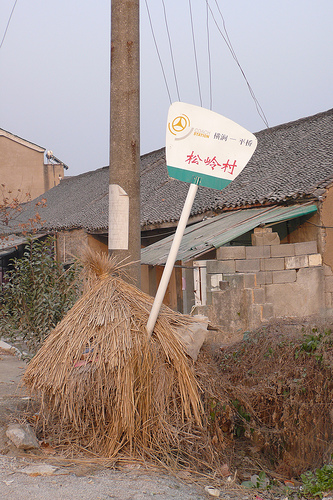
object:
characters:
[237, 137, 247, 149]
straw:
[12, 231, 227, 477]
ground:
[0, 328, 332, 500]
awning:
[138, 203, 322, 267]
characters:
[220, 158, 239, 179]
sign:
[164, 101, 259, 192]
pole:
[144, 183, 196, 338]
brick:
[293, 241, 316, 260]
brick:
[258, 258, 283, 273]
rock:
[4, 424, 41, 453]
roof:
[0, 110, 332, 235]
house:
[0, 110, 332, 364]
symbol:
[166, 112, 195, 141]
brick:
[242, 271, 256, 286]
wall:
[193, 238, 323, 347]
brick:
[231, 272, 255, 288]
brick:
[252, 232, 279, 247]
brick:
[245, 243, 270, 262]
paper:
[107, 184, 129, 249]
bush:
[0, 233, 82, 357]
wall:
[53, 231, 85, 274]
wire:
[204, 0, 214, 111]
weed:
[297, 461, 332, 498]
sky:
[0, 0, 332, 177]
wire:
[142, 0, 170, 106]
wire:
[160, 0, 180, 101]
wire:
[189, 0, 202, 106]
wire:
[205, 0, 212, 114]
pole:
[109, 0, 138, 289]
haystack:
[25, 250, 202, 457]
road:
[0, 353, 208, 499]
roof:
[134, 204, 312, 263]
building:
[0, 125, 70, 207]